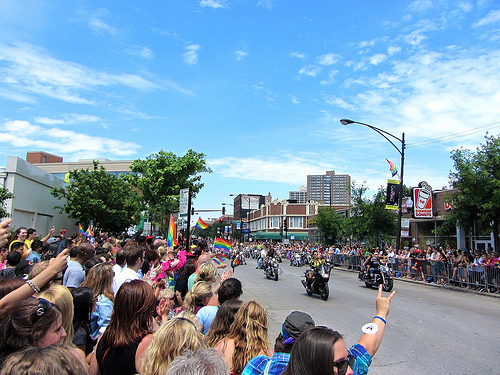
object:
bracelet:
[374, 313, 392, 326]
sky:
[0, 0, 500, 228]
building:
[244, 199, 321, 240]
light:
[220, 205, 227, 217]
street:
[214, 252, 500, 375]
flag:
[166, 213, 182, 245]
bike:
[299, 261, 333, 302]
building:
[302, 167, 352, 204]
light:
[337, 116, 353, 130]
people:
[87, 278, 161, 374]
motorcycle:
[299, 263, 335, 300]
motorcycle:
[262, 254, 283, 281]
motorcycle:
[234, 244, 246, 266]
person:
[309, 247, 323, 277]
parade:
[238, 241, 440, 314]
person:
[366, 249, 387, 277]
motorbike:
[355, 260, 397, 292]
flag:
[164, 212, 180, 250]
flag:
[195, 215, 210, 232]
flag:
[210, 235, 235, 253]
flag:
[77, 220, 89, 236]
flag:
[382, 156, 398, 179]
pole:
[392, 130, 408, 260]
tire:
[319, 280, 333, 300]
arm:
[351, 305, 395, 361]